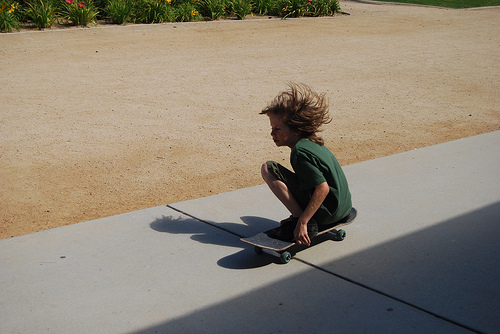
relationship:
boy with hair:
[261, 98, 360, 228] [174, 39, 361, 129]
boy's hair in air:
[179, 91, 364, 181] [385, 64, 484, 219]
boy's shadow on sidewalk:
[160, 183, 360, 283] [345, 177, 462, 315]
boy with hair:
[261, 98, 360, 228] [259, 80, 330, 150]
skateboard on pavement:
[238, 207, 366, 264] [328, 182, 458, 307]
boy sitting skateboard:
[241, 98, 360, 313] [216, 190, 376, 261]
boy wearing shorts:
[261, 98, 360, 228] [265, 170, 335, 239]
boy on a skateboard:
[261, 98, 360, 228] [218, 198, 355, 264]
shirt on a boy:
[283, 132, 346, 229] [230, 87, 360, 247]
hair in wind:
[243, 77, 347, 157] [378, 19, 468, 133]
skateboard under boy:
[238, 207, 366, 264] [229, 74, 387, 267]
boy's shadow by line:
[160, 204, 251, 249] [295, 229, 436, 314]